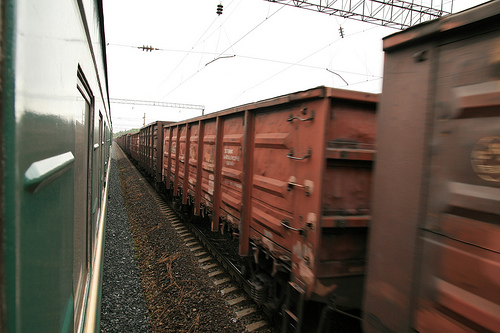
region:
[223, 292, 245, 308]
wooden crosstie on train tracks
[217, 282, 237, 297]
wooden crosstie on train tracks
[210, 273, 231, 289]
wooden crosstie on train tracks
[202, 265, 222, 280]
wooden crosstie on train tracks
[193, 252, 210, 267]
wooden crosstie on train tracks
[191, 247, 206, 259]
wooden crosstie on train tracks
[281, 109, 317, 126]
rung of a ladder on train car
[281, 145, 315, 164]
rung of a ladder on train car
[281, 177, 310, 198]
rung of a ladder on train car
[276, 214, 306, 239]
rung of a ladder on train car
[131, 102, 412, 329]
Train is in track.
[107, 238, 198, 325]
Gravel is between the track.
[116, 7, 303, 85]
Power cords are passing above the train.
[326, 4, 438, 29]
Rods are grey color.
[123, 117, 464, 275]
Goods carrier is red color.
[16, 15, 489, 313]
Day time picture.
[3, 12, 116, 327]
Train is green color.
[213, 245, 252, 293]
Track is brown color.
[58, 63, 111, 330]
Windows are in sides of train.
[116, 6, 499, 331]
train on right is metal and red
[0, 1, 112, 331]
train on left is green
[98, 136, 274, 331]
gravel inbetween trains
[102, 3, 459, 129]
power lines hang above trains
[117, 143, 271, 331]
wooden rails under tracks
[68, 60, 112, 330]
square windows on train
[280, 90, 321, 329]
metal bar ladder on car side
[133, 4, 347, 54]
power line pole seperaters on lines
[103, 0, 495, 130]
sky is overcast and light grey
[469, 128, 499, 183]
yellow paint on first car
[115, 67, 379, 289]
a long cargo tarin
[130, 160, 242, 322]
railroad tracks on the ground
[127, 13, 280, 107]
bunch of wire and power lines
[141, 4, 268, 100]
bunch of power lines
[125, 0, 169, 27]
a sky with no clouds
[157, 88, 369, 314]
a red cargo freight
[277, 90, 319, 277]
handles on a cargo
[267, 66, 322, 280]
stair handle on a cargo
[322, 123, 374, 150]
rust on a cargo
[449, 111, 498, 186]
a logo on a cargo